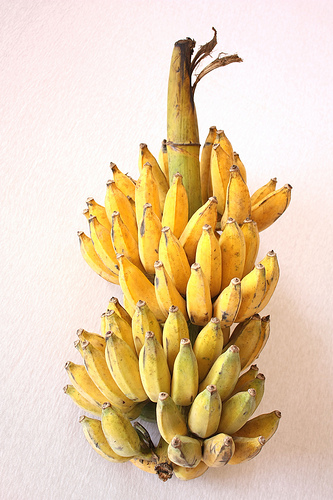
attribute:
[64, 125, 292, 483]
bananas — fresh, yellow, upside down, black, green, hanging, dark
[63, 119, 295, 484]
plantains — hanging, under, above, below, waiting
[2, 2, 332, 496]
wall — white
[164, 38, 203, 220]
stem — broken, black, greenish brown